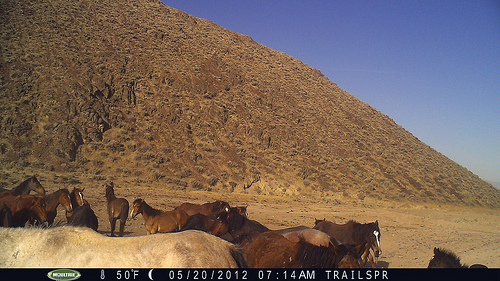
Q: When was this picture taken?
A: During the day.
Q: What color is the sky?
A: Blue.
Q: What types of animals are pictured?
A: Horses.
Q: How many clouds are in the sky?
A: Zero.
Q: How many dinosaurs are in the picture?
A: Zero.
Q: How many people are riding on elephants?
A: Zero.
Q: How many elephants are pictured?
A: Zero.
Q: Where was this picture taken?
A: In the desert.